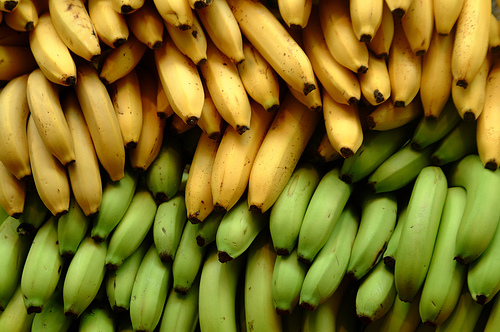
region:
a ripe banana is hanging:
[478, 61, 497, 167]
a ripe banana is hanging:
[326, 99, 361, 149]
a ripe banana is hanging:
[246, 90, 326, 227]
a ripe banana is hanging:
[218, 108, 288, 211]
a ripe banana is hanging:
[184, 126, 223, 249]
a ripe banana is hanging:
[153, 44, 203, 135]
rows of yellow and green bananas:
[3, 2, 499, 329]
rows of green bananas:
[11, 134, 485, 327]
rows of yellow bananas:
[6, 4, 497, 204]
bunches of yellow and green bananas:
[5, 2, 488, 330]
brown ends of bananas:
[3, 1, 496, 321]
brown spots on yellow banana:
[62, 6, 90, 43]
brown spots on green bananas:
[153, 198, 180, 253]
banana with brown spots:
[240, 6, 315, 89]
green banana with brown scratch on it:
[419, 187, 470, 322]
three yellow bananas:
[167, 118, 304, 216]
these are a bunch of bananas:
[50, 28, 472, 308]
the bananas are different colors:
[94, 41, 464, 298]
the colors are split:
[62, 34, 364, 284]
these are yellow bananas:
[77, 33, 434, 173]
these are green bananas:
[98, 197, 379, 278]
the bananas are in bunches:
[92, 60, 412, 284]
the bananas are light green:
[80, 220, 451, 302]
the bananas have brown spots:
[31, 20, 496, 208]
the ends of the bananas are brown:
[108, 74, 450, 205]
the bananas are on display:
[82, 40, 406, 215]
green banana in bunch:
[1, 213, 30, 315]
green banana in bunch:
[18, 223, 62, 313]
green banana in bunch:
[58, 203, 85, 255]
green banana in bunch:
[61, 236, 105, 314]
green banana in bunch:
[90, 163, 132, 241]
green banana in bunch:
[101, 188, 155, 273]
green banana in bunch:
[129, 248, 167, 330]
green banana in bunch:
[155, 198, 183, 265]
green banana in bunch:
[168, 216, 203, 298]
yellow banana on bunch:
[247, 107, 314, 221]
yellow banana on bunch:
[323, 88, 363, 159]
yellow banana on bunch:
[366, 95, 416, 132]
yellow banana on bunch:
[248, 103, 318, 211]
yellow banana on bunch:
[211, 106, 271, 212]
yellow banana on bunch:
[184, 128, 223, 228]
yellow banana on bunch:
[73, 68, 129, 185]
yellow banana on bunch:
[61, 101, 101, 220]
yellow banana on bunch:
[27, 111, 70, 218]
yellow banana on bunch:
[26, 68, 78, 168]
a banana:
[20, 229, 62, 296]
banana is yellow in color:
[27, 65, 73, 148]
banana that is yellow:
[78, 72, 129, 177]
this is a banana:
[287, 172, 348, 258]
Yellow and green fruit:
[96, 128, 450, 305]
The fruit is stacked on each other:
[111, 113, 476, 289]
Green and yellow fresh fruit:
[186, 90, 443, 225]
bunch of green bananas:
[450, 170, 497, 323]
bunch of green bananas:
[401, 172, 447, 307]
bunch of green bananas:
[300, 180, 341, 265]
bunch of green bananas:
[212, 252, 284, 327]